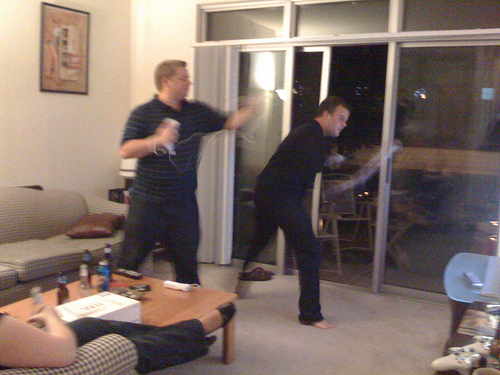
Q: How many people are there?
A: Three.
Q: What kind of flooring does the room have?
A: Carpet.